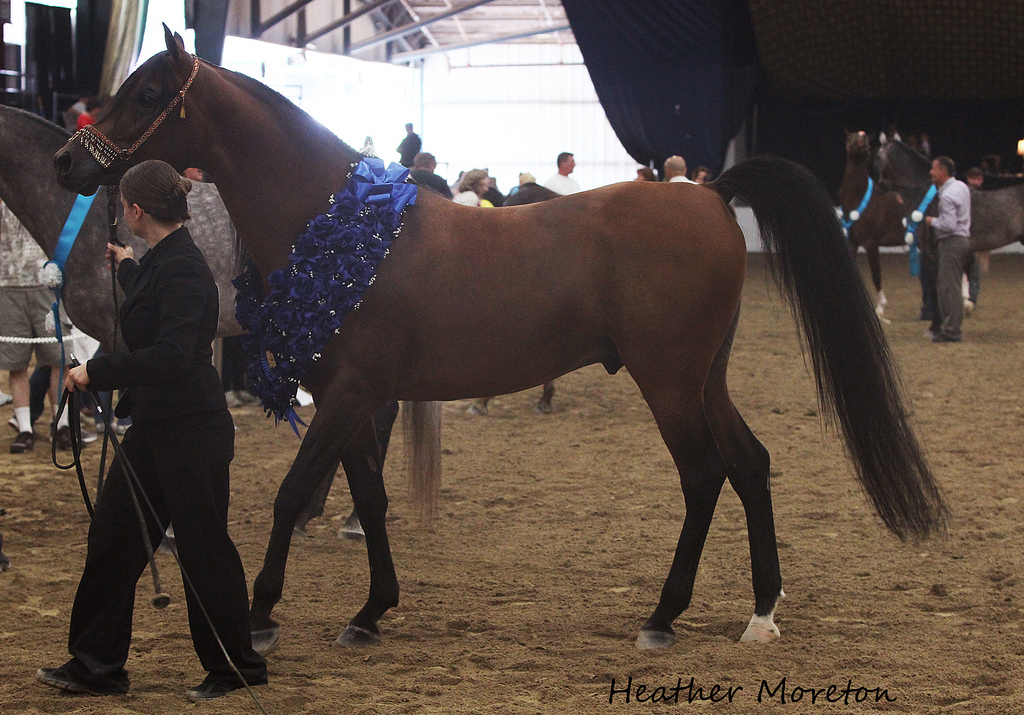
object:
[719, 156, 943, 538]
tail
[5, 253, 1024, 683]
sand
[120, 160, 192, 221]
hair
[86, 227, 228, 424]
jacket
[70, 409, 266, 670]
pants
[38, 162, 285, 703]
person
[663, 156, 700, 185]
person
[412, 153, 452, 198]
person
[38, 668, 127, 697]
shoes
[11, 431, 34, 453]
shoes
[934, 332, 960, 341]
shoes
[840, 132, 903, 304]
horse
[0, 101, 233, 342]
horse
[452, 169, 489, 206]
person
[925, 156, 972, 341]
man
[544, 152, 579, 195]
man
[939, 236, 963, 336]
pants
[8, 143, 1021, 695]
pen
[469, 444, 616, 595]
dirt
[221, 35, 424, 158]
wall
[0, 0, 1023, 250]
building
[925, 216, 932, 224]
hand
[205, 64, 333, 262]
neck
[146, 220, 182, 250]
neck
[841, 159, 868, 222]
neck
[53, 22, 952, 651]
horse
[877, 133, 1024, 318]
horse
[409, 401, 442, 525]
tail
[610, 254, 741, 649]
legs